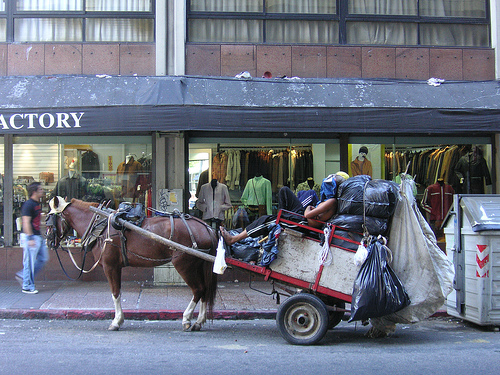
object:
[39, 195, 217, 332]
horse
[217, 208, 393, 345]
wheelbarrow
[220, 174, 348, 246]
man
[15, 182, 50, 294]
man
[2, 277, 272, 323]
sidewalk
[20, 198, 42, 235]
t-shirt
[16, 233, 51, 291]
jeans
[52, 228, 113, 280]
reins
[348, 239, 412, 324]
bags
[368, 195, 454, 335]
bag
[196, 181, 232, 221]
clothes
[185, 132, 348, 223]
window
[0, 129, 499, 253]
shop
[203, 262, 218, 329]
tail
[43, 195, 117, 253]
gear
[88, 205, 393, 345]
cart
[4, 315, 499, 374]
road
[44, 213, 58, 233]
blinders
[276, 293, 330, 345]
wheel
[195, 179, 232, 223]
manequin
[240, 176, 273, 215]
shirt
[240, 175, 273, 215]
manequin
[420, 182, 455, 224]
jacket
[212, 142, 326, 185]
rack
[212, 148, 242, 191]
jackets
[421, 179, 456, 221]
manequin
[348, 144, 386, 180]
poster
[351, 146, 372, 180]
man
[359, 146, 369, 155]
hat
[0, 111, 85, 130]
name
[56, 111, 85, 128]
letters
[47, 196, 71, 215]
hat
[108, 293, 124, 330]
white sox